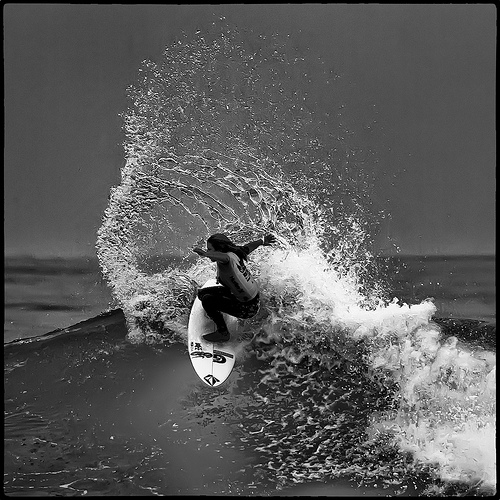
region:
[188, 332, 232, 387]
A surf board in the water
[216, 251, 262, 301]
Gray top in the photo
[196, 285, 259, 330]
Black pants in the photo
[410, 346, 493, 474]
Waves in the water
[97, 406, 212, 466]
Ocean waters in the photo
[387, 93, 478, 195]
Dark clouds in the photo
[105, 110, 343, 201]
Water splashing in the air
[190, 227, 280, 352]
A woman surfing in the water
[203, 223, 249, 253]
A long black hair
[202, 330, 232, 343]
Gray shoe in the photo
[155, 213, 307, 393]
young person surfing in ocean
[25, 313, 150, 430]
white and blue waves in ocean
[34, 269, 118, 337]
white and blue waves in ocean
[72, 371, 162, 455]
white and blue waves in ocean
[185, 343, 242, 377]
surf board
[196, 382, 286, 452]
white and blue waves in ocean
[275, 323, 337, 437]
white and blue waves in ocean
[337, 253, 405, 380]
white and blue waves in ocean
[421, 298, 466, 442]
white and blue waves in ocean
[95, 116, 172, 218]
spray in ocean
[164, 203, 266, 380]
person surfing on board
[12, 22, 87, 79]
white clouds against blue sky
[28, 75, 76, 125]
white clouds against blue sky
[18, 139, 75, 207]
white clouds against blue sky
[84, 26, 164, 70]
white clouds against blue sky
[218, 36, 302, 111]
white clouds against blue sky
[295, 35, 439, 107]
white clouds against blue sky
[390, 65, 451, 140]
white clouds against blue sky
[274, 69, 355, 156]
white clouds against blue sky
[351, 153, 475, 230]
white clouds against blue sky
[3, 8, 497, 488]
black and white photo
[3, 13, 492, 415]
woman riding wave on surfboard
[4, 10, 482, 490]
water crashing high above the rider's head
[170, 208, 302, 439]
woman with hands to the side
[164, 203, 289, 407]
woman on white surf board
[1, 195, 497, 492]
white cap waves in water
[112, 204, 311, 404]
woman concentrating on surfing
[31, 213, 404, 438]
woman with long hair on board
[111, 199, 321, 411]
advertising on woman's wet suit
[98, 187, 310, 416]
bottom of board pointed toward water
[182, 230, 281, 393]
Woman on a surfboard surfing a wave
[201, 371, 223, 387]
Volcom logo on a white surfboard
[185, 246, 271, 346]
Wet suit on a woman surfing a wave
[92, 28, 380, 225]
Wave splash off of a surfboard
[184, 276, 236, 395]
White surfboard with company logos on it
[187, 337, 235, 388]
Company logos on a white surfboard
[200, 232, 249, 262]
Hair of a woman on a white surfboard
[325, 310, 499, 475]
Wave crashing near a surfer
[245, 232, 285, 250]
Arm of a surfer to keep balance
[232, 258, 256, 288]
Logo on the back of a wetsuit